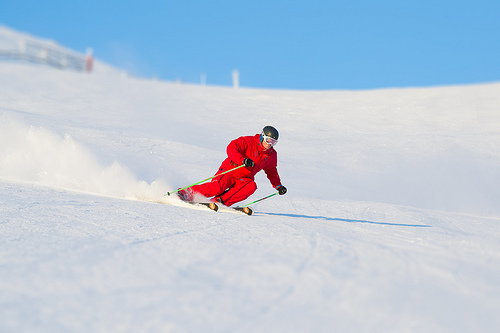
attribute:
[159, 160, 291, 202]
ski poles — neon green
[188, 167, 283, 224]
pants — red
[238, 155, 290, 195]
gloves — black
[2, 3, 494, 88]
sky — blue, clear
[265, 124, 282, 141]
helmet — black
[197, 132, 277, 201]
jumpsuit — orange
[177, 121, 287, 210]
guy — skiing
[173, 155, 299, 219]
poles — green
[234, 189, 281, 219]
pole — silver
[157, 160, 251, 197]
pole — silver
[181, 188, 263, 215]
skis — black, yellow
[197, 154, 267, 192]
pole — ski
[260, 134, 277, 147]
goggles — pictured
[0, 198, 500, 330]
snow — thick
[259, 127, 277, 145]
goggles — white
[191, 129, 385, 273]
he — fast-skiing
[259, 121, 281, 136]
helmet — black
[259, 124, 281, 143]
helmet — black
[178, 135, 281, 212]
clothes — red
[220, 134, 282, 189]
jacket — red